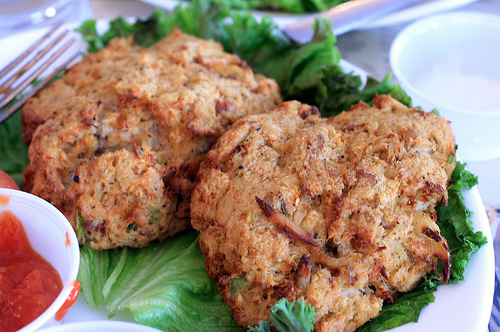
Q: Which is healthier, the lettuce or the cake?
A: The lettuce is healthier than the cake.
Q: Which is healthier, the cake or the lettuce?
A: The lettuce is healthier than the cake.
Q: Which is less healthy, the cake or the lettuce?
A: The cake is less healthy than the lettuce.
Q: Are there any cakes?
A: Yes, there is a cake.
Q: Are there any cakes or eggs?
A: Yes, there is a cake.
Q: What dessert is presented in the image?
A: The dessert is a cake.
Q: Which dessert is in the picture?
A: The dessert is a cake.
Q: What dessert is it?
A: The dessert is a cake.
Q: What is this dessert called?
A: That is a cake.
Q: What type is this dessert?
A: That is a cake.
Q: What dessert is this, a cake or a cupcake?
A: That is a cake.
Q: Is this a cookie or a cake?
A: This is a cake.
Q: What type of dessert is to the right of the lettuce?
A: The dessert is a cake.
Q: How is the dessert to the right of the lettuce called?
A: The dessert is a cake.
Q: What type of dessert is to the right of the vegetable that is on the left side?
A: The dessert is a cake.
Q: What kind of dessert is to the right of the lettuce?
A: The dessert is a cake.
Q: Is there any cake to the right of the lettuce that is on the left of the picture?
A: Yes, there is a cake to the right of the lettuce.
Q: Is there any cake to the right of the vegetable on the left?
A: Yes, there is a cake to the right of the lettuce.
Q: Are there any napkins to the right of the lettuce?
A: No, there is a cake to the right of the lettuce.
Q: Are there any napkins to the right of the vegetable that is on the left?
A: No, there is a cake to the right of the lettuce.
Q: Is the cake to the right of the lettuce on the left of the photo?
A: Yes, the cake is to the right of the lettuce.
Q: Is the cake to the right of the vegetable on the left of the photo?
A: Yes, the cake is to the right of the lettuce.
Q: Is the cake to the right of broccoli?
A: No, the cake is to the right of the lettuce.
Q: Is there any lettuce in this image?
A: Yes, there is lettuce.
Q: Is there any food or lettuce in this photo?
A: Yes, there is lettuce.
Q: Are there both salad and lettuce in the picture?
A: No, there is lettuce but no salad.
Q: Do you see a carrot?
A: No, there are no carrots.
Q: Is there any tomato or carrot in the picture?
A: No, there are no carrots or tomatoes.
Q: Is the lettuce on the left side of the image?
A: Yes, the lettuce is on the left of the image.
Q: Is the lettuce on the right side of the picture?
A: No, the lettuce is on the left of the image.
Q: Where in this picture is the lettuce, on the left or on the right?
A: The lettuce is on the left of the image.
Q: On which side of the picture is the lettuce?
A: The lettuce is on the left of the image.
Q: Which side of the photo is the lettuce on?
A: The lettuce is on the left of the image.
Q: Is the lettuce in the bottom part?
A: Yes, the lettuce is in the bottom of the image.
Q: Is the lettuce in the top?
A: No, the lettuce is in the bottom of the image.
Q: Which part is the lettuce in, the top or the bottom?
A: The lettuce is in the bottom of the image.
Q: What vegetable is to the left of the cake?
A: The vegetable is lettuce.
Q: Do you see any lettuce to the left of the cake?
A: Yes, there is lettuce to the left of the cake.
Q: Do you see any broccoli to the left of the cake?
A: No, there is lettuce to the left of the cake.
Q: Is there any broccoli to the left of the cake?
A: No, there is lettuce to the left of the cake.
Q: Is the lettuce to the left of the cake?
A: Yes, the lettuce is to the left of the cake.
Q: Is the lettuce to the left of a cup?
A: No, the lettuce is to the left of the cake.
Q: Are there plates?
A: Yes, there is a plate.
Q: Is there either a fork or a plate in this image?
A: Yes, there is a plate.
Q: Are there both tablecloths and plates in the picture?
A: No, there is a plate but no tablecloths.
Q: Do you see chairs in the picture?
A: No, there are no chairs.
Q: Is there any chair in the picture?
A: No, there are no chairs.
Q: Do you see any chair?
A: No, there are no chairs.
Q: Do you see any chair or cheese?
A: No, there are no chairs or cheese.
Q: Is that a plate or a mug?
A: That is a plate.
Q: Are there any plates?
A: Yes, there is a plate.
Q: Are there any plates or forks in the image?
A: Yes, there is a plate.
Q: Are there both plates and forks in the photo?
A: Yes, there are both a plate and a fork.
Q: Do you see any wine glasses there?
A: No, there are no wine glasses.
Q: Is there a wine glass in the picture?
A: No, there are no wine glasses.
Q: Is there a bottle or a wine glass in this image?
A: No, there are no wine glasses or bottles.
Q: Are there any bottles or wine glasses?
A: No, there are no wine glasses or bottles.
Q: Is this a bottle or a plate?
A: This is a plate.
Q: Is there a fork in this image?
A: Yes, there is a fork.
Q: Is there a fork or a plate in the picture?
A: Yes, there is a fork.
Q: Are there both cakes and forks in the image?
A: Yes, there are both a fork and a cake.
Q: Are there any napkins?
A: No, there are no napkins.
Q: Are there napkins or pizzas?
A: No, there are no napkins or pizzas.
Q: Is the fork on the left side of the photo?
A: Yes, the fork is on the left of the image.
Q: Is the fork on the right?
A: No, the fork is on the left of the image.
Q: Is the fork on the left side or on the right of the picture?
A: The fork is on the left of the image.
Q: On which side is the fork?
A: The fork is on the left of the image.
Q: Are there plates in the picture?
A: Yes, there is a plate.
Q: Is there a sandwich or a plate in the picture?
A: Yes, there is a plate.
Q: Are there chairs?
A: No, there are no chairs.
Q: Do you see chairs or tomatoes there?
A: No, there are no chairs or tomatoes.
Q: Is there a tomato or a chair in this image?
A: No, there are no chairs or tomatoes.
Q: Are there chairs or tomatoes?
A: No, there are no chairs or tomatoes.